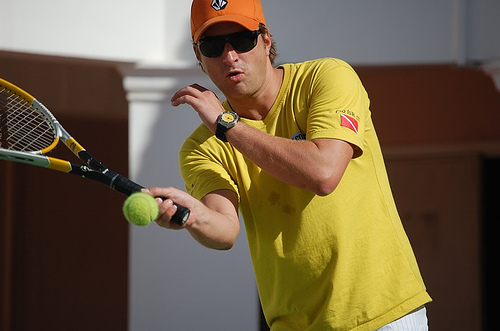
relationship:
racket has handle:
[1, 79, 192, 228] [114, 163, 192, 225]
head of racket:
[1, 76, 68, 182] [1, 79, 192, 228]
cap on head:
[193, 3, 266, 50] [192, 22, 273, 104]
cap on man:
[193, 3, 266, 50] [145, 1, 428, 329]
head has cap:
[192, 22, 273, 104] [193, 3, 266, 50]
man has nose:
[145, 1, 428, 329] [223, 46, 238, 65]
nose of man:
[223, 46, 238, 65] [145, 1, 428, 329]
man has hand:
[145, 1, 428, 329] [172, 80, 222, 131]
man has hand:
[145, 1, 428, 329] [147, 190, 203, 230]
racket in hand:
[1, 79, 192, 228] [147, 190, 203, 230]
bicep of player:
[203, 193, 240, 221] [145, 1, 428, 329]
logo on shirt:
[337, 116, 363, 134] [179, 50, 435, 330]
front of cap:
[192, 17, 258, 43] [193, 3, 266, 50]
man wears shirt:
[145, 1, 428, 329] [179, 50, 435, 330]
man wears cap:
[145, 1, 428, 329] [193, 3, 266, 50]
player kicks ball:
[145, 1, 428, 329] [125, 190, 161, 228]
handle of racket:
[114, 163, 192, 225] [1, 79, 192, 228]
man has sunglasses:
[145, 1, 428, 329] [193, 29, 260, 57]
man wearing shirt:
[145, 1, 428, 329] [179, 50, 435, 330]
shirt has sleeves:
[179, 50, 435, 330] [307, 59, 370, 155]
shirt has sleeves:
[179, 50, 435, 330] [179, 144, 241, 206]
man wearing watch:
[145, 1, 428, 329] [214, 114, 240, 143]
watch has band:
[214, 114, 240, 143] [217, 122, 226, 141]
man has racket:
[145, 1, 428, 329] [1, 79, 192, 228]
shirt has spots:
[179, 50, 435, 330] [265, 191, 278, 206]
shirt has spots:
[179, 50, 435, 330] [282, 206, 296, 216]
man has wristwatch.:
[145, 1, 428, 329] [214, 114, 240, 143]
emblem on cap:
[212, 2, 229, 13] [193, 3, 266, 50]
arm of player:
[169, 83, 358, 198] [186, 20, 469, 318]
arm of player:
[134, 185, 239, 254] [161, 32, 306, 246]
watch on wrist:
[196, 90, 251, 147] [214, 114, 240, 143]